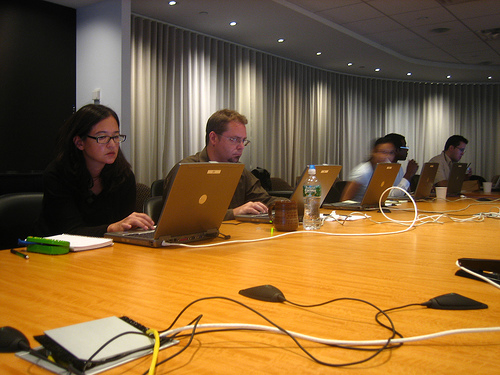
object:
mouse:
[237, 284, 283, 303]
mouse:
[0, 323, 30, 354]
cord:
[153, 296, 402, 367]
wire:
[308, 337, 393, 346]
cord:
[163, 236, 274, 248]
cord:
[144, 328, 163, 375]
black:
[447, 297, 461, 306]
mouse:
[420, 292, 488, 312]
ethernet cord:
[460, 210, 494, 223]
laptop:
[104, 162, 245, 248]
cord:
[318, 186, 475, 238]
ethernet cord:
[399, 187, 417, 209]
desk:
[3, 188, 500, 375]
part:
[305, 253, 386, 297]